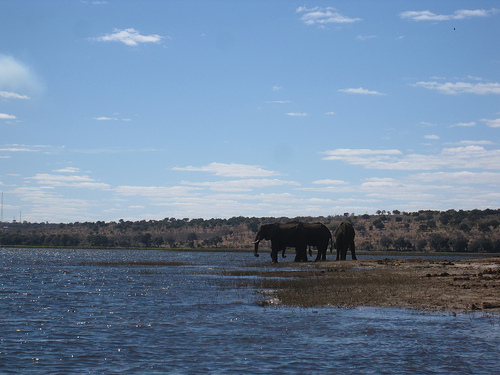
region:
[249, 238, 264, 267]
nose of an elephant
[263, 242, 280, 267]
leg of an elephant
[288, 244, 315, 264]
leg of an elephant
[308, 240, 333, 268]
leg of an elephant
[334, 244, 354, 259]
leg of an elephant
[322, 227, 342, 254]
tail of an elephant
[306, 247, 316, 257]
tail of an elephant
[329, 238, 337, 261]
nose of an elephant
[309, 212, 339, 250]
body of an elephant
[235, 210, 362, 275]
A herd of elephant by a body of water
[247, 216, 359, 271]
A herd of elephant by a body of water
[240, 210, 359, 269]
A herd of elephant by a body of water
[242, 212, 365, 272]
A herd of elephant by a body of water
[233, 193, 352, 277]
elephant near the water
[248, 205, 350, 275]
elephant near the water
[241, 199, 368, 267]
elephant near the water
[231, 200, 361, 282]
elephant near the water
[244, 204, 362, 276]
elephant near the water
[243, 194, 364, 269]
elephant near the water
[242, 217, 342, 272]
elephant near the water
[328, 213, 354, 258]
elephant near the water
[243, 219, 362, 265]
two large elephants standing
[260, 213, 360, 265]
three elephants standing together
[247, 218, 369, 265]
group of elehpants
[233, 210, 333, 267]
elephants by water source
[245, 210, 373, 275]
elephants standing on shore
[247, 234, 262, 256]
long trunk of elephant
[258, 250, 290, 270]
thick long legs of elephant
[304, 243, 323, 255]
small grey tail hanging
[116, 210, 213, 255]
bushes on hillside in back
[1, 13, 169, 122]
white clouds in blue sky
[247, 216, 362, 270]
the elephants on the water bank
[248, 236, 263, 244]
the tusk on the elephants face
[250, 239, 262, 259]
the trunk of the elephant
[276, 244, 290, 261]
the trunk under the elephant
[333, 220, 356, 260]
the back of the elephant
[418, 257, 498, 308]
the dirt clumps on the sand bar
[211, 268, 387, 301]
the tall gras son the bank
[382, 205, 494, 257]
the trees on the hillside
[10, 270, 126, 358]
the sun glimmering off the water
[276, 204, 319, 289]
an elephant is outside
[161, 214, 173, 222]
green leaves on the tree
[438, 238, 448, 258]
green leaves on the tree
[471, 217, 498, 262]
green leaves on the tree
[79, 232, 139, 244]
green leaves on the tree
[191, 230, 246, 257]
green leaves on the tree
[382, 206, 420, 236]
green leaves on the tree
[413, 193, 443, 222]
green leaves on the tree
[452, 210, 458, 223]
green leaves on the tree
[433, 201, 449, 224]
green leaves on the tree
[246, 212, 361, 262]
elephants near the water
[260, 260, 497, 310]
dirt beside the water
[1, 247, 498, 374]
dark blue water near the elephants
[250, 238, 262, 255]
trunk of the elephant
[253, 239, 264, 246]
white tusks of the elephant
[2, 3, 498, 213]
blue sky with scattered white clouds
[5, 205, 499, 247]
trees behind the elephants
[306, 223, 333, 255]
tails of the elephants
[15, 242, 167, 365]
light reflection on the water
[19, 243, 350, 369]
ripples in the water